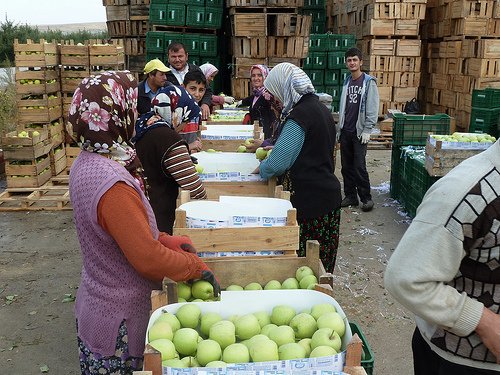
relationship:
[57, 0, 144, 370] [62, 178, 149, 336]
woman wearing shirt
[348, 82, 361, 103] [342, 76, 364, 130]
white letters on shirt